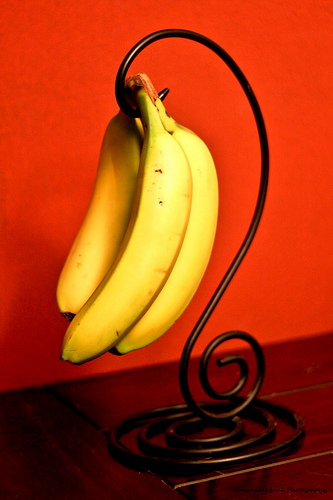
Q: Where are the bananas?
A: Hanging from a metal holder.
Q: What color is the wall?
A: Red.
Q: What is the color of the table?
A: Brown.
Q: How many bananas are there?
A: 3.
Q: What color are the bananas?
A: Yellow.